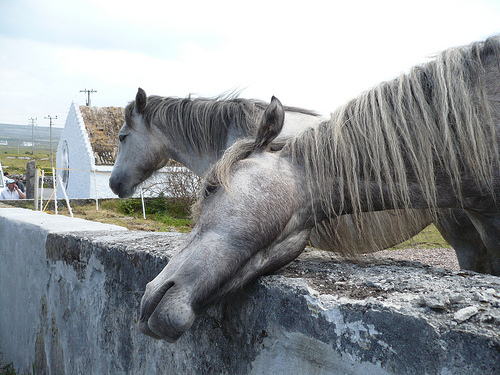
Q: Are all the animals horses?
A: Yes, all the animals are horses.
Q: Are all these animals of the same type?
A: Yes, all the animals are horses.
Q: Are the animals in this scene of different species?
A: No, all the animals are horses.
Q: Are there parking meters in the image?
A: No, there are no parking meters.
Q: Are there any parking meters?
A: No, there are no parking meters.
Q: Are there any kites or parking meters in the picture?
A: No, there are no parking meters or kites.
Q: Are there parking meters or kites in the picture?
A: No, there are no parking meters or kites.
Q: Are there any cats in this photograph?
A: No, there are no cats.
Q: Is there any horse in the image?
A: Yes, there are horses.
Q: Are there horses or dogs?
A: Yes, there are horses.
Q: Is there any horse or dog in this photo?
A: Yes, there are horses.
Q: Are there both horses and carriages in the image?
A: No, there are horses but no carriages.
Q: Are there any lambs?
A: No, there are no lambs.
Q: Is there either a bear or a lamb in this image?
A: No, there are no lambs or bears.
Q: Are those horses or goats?
A: Those are horses.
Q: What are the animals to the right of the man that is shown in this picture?
A: The animals are horses.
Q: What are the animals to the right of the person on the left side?
A: The animals are horses.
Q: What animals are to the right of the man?
A: The animals are horses.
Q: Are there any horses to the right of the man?
A: Yes, there are horses to the right of the man.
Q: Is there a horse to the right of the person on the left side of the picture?
A: Yes, there are horses to the right of the man.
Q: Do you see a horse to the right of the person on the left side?
A: Yes, there are horses to the right of the man.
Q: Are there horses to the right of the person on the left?
A: Yes, there are horses to the right of the man.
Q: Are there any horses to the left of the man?
A: No, the horses are to the right of the man.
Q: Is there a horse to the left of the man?
A: No, the horses are to the right of the man.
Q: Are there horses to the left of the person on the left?
A: No, the horses are to the right of the man.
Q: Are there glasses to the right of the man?
A: No, there are horses to the right of the man.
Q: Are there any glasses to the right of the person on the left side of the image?
A: No, there are horses to the right of the man.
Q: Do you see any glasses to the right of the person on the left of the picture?
A: No, there are horses to the right of the man.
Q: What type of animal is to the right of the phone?
A: The animals are horses.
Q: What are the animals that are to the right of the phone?
A: The animals are horses.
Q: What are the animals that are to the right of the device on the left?
A: The animals are horses.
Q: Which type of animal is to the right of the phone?
A: The animals are horses.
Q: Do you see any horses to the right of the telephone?
A: Yes, there are horses to the right of the telephone.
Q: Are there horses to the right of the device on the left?
A: Yes, there are horses to the right of the telephone.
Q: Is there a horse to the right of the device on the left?
A: Yes, there are horses to the right of the telephone.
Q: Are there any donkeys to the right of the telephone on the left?
A: No, there are horses to the right of the phone.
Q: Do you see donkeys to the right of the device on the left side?
A: No, there are horses to the right of the phone.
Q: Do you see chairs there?
A: No, there are no chairs.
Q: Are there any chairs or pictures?
A: No, there are no chairs or pictures.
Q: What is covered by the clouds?
A: The sky is covered by the clouds.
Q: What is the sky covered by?
A: The sky is covered by the clouds.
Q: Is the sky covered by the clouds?
A: Yes, the sky is covered by the clouds.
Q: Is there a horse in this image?
A: Yes, there is a horse.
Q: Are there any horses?
A: Yes, there is a horse.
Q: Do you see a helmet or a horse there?
A: Yes, there is a horse.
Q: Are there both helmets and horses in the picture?
A: No, there is a horse but no helmets.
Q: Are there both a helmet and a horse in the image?
A: No, there is a horse but no helmets.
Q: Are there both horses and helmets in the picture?
A: No, there is a horse but no helmets.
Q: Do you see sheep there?
A: No, there are no sheep.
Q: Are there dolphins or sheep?
A: No, there are no sheep or dolphins.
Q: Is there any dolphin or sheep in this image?
A: No, there are no sheep or dolphins.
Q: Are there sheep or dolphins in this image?
A: No, there are no sheep or dolphins.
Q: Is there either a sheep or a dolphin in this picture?
A: No, there are no sheep or dolphins.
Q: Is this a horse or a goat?
A: This is a horse.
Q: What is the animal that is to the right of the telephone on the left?
A: The animal is a horse.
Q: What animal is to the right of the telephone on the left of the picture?
A: The animal is a horse.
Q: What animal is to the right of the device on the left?
A: The animal is a horse.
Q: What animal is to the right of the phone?
A: The animal is a horse.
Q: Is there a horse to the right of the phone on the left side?
A: Yes, there is a horse to the right of the phone.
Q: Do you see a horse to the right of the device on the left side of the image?
A: Yes, there is a horse to the right of the phone.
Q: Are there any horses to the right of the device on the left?
A: Yes, there is a horse to the right of the phone.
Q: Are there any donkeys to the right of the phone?
A: No, there is a horse to the right of the phone.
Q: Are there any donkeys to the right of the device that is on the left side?
A: No, there is a horse to the right of the phone.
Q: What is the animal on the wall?
A: The animal is a horse.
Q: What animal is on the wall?
A: The animal is a horse.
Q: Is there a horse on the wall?
A: Yes, there is a horse on the wall.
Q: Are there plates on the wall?
A: No, there is a horse on the wall.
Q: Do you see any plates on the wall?
A: No, there is a horse on the wall.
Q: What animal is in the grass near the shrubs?
A: The horse is in the grass.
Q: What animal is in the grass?
A: The horse is in the grass.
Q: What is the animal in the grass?
A: The animal is a horse.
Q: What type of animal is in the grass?
A: The animal is a horse.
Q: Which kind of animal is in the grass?
A: The animal is a horse.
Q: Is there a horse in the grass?
A: Yes, there is a horse in the grass.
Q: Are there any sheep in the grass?
A: No, there is a horse in the grass.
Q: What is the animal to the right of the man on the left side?
A: The animal is a horse.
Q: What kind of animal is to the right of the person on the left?
A: The animal is a horse.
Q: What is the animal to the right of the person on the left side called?
A: The animal is a horse.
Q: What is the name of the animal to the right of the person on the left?
A: The animal is a horse.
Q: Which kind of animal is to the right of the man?
A: The animal is a horse.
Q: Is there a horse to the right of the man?
A: Yes, there is a horse to the right of the man.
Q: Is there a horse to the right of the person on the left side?
A: Yes, there is a horse to the right of the man.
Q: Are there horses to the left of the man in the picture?
A: No, the horse is to the right of the man.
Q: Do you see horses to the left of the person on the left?
A: No, the horse is to the right of the man.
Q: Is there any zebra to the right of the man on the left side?
A: No, there is a horse to the right of the man.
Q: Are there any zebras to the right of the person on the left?
A: No, there is a horse to the right of the man.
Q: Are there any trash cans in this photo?
A: No, there are no trash cans.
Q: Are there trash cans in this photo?
A: No, there are no trash cans.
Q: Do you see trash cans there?
A: No, there are no trash cans.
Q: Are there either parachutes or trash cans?
A: No, there are no trash cans or parachutes.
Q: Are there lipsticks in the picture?
A: No, there are no lipsticks.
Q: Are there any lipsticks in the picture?
A: No, there are no lipsticks.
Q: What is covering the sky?
A: The clouds are covering the sky.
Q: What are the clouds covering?
A: The clouds are covering the sky.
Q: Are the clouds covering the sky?
A: Yes, the clouds are covering the sky.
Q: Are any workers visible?
A: No, there are no workers.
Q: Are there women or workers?
A: No, there are no workers or women.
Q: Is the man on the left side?
A: Yes, the man is on the left of the image.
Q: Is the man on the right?
A: No, the man is on the left of the image.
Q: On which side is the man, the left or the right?
A: The man is on the left of the image.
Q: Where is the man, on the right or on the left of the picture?
A: The man is on the left of the image.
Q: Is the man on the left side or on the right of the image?
A: The man is on the left of the image.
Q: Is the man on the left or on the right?
A: The man is on the left of the image.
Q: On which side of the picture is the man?
A: The man is on the left of the image.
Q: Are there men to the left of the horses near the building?
A: Yes, there is a man to the left of the horses.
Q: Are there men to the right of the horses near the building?
A: No, the man is to the left of the horses.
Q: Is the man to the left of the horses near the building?
A: Yes, the man is to the left of the horses.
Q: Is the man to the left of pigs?
A: No, the man is to the left of the horses.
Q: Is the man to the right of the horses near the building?
A: No, the man is to the left of the horses.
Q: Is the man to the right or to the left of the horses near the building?
A: The man is to the left of the horses.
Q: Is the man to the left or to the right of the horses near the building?
A: The man is to the left of the horses.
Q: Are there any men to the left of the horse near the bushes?
A: Yes, there is a man to the left of the horse.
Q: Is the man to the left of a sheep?
A: No, the man is to the left of the horse.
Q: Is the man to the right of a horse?
A: No, the man is to the left of a horse.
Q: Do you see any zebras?
A: No, there are no zebras.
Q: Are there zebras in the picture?
A: No, there are no zebras.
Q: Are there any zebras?
A: No, there are no zebras.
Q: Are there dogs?
A: No, there are no dogs.